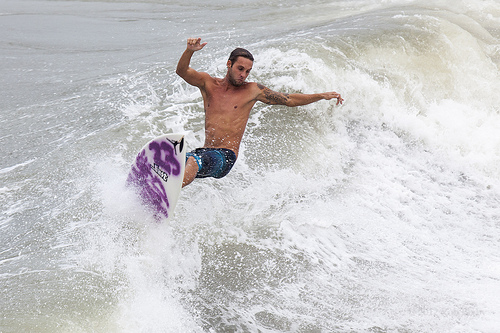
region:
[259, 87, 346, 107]
an outstretched arm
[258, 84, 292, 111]
a tattoo on a mans arm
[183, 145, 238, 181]
a pair of blue surfboard shorts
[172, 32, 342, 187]
a surfer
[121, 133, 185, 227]
a white surfboard with purple grafitti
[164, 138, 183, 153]
a black Nike Jordan emblem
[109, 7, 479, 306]
a wave in the ocean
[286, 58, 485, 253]
sea foam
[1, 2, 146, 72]
calmer water behind the tide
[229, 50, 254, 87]
a mans intense face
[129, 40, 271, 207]
surfing man in water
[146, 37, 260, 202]
surfer in water with a purple board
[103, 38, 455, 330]
white wave in sea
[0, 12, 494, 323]
sea where surfer guy is standing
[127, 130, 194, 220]
small purple surfboard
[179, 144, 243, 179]
blue and black pants in a surfer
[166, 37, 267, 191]
man with two arms open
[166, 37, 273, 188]
surfer with blue and black pants and no shirt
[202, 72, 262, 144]
chest of a surfer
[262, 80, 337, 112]
tattoed left arm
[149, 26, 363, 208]
a surfer in the sea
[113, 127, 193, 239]
board is white and purple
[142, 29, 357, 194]
surfer has extended hands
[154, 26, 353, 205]
surfer wears a blue short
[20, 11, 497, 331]
water of sea is choppy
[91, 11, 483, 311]
a big wave in the ocean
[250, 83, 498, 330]
foamy water in the sea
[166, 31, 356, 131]
boy has a tattoo on left arm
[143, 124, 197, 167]
a black design on tip of nose of surfboard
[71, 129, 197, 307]
splash of water in the sea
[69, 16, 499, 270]
the wave on the ocean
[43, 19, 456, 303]
the ocean is raging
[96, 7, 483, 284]
the wave is large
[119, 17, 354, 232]
the man on the surfboard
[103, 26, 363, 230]
the man is surfing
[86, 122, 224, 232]
the surfboard is white and purple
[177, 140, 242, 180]
the shorts are blue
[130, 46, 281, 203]
the man wearing shorts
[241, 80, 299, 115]
the tattoo on the arm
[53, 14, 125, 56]
the ocean is opaque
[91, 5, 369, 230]
a man on a surfboard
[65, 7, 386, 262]
a man on a white surfboard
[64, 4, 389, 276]
a man on a wave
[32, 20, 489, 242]
a man on a white wave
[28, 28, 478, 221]
a man on the water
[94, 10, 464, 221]
a man with no shirt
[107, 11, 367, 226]
a man wearing swim trunks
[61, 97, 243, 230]
a white surfboard with spray paint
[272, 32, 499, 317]
a body of water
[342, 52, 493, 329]
a body of water with waves